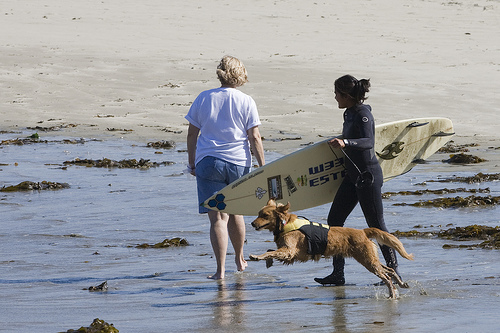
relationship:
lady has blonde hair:
[183, 56, 265, 281] [206, 54, 250, 84]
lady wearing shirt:
[183, 56, 265, 281] [187, 82, 257, 165]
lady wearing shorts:
[183, 56, 265, 281] [189, 150, 253, 214]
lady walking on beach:
[183, 56, 265, 281] [0, 3, 497, 331]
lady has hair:
[312, 70, 402, 286] [334, 73, 373, 107]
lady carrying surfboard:
[312, 70, 402, 286] [202, 125, 449, 210]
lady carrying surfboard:
[312, 70, 402, 286] [203, 115, 455, 216]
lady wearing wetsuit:
[324, 70, 390, 141] [340, 110, 378, 175]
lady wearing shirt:
[183, 56, 265, 281] [186, 88, 261, 167]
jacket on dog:
[297, 222, 327, 257] [248, 198, 414, 298]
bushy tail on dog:
[358, 224, 412, 261] [248, 198, 414, 298]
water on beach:
[2, 131, 499, 331] [0, 3, 497, 331]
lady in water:
[183, 56, 265, 281] [2, 131, 499, 331]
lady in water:
[312, 70, 402, 286] [2, 131, 499, 331]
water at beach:
[2, 131, 499, 331] [6, 8, 193, 129]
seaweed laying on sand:
[381, 167, 498, 250] [4, 1, 499, 168]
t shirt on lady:
[158, 77, 268, 164] [183, 56, 265, 281]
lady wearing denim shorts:
[183, 56, 265, 281] [191, 156, 249, 214]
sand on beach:
[0, 1, 499, 330] [0, 3, 497, 331]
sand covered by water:
[0, 1, 499, 330] [2, 131, 499, 331]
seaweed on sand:
[381, 167, 498, 250] [0, 1, 499, 330]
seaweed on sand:
[56, 154, 176, 173] [0, 1, 499, 330]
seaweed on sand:
[6, 180, 71, 195] [0, 1, 499, 330]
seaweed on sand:
[62, 316, 122, 331] [0, 1, 499, 330]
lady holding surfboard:
[312, 70, 402, 286] [208, 119, 435, 220]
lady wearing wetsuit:
[312, 70, 402, 286] [298, 85, 400, 286]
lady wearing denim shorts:
[183, 56, 265, 281] [180, 166, 249, 214]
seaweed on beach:
[56, 154, 176, 173] [0, 3, 497, 331]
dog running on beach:
[246, 204, 420, 282] [201, 273, 418, 307]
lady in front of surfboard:
[181, 47, 271, 287] [196, 111, 459, 223]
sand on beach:
[0, 1, 499, 330] [3, 52, 498, 192]